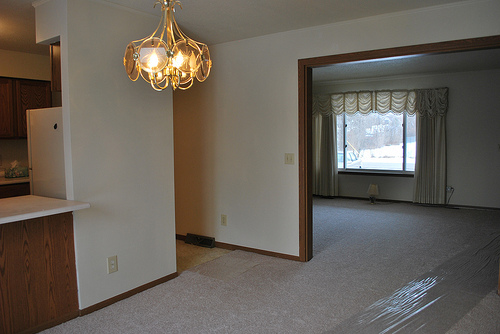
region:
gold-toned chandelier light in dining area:
[122, 1, 219, 93]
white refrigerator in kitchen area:
[24, 103, 69, 204]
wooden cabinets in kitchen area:
[0, 43, 72, 138]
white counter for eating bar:
[1, 191, 96, 224]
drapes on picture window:
[308, 84, 455, 206]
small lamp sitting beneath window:
[365, 184, 385, 206]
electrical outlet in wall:
[105, 251, 120, 276]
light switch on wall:
[280, 147, 296, 164]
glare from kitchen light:
[1, 15, 23, 42]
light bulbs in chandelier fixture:
[146, 48, 187, 68]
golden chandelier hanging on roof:
[107, 4, 232, 93]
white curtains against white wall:
[313, 86, 464, 211]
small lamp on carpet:
[349, 176, 396, 220]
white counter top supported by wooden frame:
[3, 193, 103, 233]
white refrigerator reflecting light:
[14, 96, 75, 210]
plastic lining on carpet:
[302, 201, 492, 330]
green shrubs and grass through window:
[330, 94, 430, 179]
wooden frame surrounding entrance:
[272, 39, 497, 288]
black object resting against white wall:
[178, 195, 317, 250]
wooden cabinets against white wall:
[4, 60, 56, 147]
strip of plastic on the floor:
[326, 235, 496, 332]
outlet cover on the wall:
[106, 252, 116, 273]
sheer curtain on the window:
[311, 86, 447, 206]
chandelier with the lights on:
[123, 3, 211, 91]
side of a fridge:
[25, 107, 67, 197]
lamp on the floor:
[366, 183, 378, 204]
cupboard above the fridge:
[48, 39, 61, 94]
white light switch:
[282, 153, 295, 165]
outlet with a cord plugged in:
[446, 184, 452, 194]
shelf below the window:
[336, 168, 415, 177]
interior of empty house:
[3, 1, 498, 331]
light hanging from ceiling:
[123, 1, 210, 89]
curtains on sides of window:
[315, 86, 448, 200]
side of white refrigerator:
[27, 104, 67, 196]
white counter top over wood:
[1, 192, 86, 332]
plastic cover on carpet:
[332, 226, 497, 332]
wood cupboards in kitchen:
[1, 76, 49, 134]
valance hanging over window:
[312, 86, 450, 117]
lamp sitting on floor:
[365, 183, 381, 202]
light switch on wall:
[284, 151, 295, 166]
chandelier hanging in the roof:
[120, 6, 212, 94]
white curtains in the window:
[310, 83, 452, 194]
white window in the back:
[333, 93, 426, 173]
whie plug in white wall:
[105, 251, 120, 278]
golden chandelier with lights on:
[119, 1, 210, 91]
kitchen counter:
[0, 188, 85, 333]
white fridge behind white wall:
[22, 103, 69, 195]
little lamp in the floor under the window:
[365, 182, 385, 205]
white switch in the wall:
[283, 151, 296, 163]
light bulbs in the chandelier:
[144, 50, 189, 68]